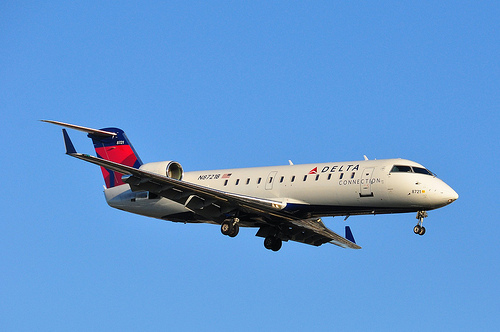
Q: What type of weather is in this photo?
A: It is clear.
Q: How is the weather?
A: It is clear.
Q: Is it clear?
A: Yes, it is clear.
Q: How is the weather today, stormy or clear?
A: It is clear.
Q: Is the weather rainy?
A: No, it is clear.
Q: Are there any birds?
A: No, there are no birds.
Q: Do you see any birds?
A: No, there are no birds.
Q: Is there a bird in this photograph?
A: No, there are no birds.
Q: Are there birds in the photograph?
A: No, there are no birds.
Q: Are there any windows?
A: Yes, there is a window.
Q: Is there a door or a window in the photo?
A: Yes, there is a window.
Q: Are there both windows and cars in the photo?
A: No, there is a window but no cars.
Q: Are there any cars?
A: No, there are no cars.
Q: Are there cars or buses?
A: No, there are no cars or buses.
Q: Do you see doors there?
A: Yes, there is a door.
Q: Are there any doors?
A: Yes, there is a door.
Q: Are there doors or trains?
A: Yes, there is a door.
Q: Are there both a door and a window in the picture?
A: Yes, there are both a door and a window.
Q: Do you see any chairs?
A: No, there are no chairs.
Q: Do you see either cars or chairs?
A: No, there are no chairs or cars.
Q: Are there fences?
A: No, there are no fences.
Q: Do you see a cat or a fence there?
A: No, there are no fences or cats.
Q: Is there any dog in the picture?
A: No, there are no dogs.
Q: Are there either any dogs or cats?
A: No, there are no dogs or cats.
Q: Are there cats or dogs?
A: No, there are no dogs or cats.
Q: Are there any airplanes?
A: Yes, there is an airplane.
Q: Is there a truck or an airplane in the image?
A: Yes, there is an airplane.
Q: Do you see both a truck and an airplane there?
A: No, there is an airplane but no trucks.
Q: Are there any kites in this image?
A: No, there are no kites.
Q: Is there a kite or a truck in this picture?
A: No, there are no kites or trucks.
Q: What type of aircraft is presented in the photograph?
A: The aircraft is an airplane.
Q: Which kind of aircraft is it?
A: The aircraft is an airplane.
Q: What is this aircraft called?
A: This is an airplane.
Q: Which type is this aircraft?
A: This is an airplane.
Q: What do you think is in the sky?
A: The airplane is in the sky.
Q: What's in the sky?
A: The airplane is in the sky.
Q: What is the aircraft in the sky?
A: The aircraft is an airplane.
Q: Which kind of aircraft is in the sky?
A: The aircraft is an airplane.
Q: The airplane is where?
A: The airplane is in the sky.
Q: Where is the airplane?
A: The airplane is in the sky.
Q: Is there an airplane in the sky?
A: Yes, there is an airplane in the sky.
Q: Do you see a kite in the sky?
A: No, there is an airplane in the sky.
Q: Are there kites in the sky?
A: No, there is an airplane in the sky.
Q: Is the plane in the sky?
A: Yes, the plane is in the sky.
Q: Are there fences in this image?
A: No, there are no fences.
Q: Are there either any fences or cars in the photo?
A: No, there are no fences or cars.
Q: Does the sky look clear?
A: Yes, the sky is clear.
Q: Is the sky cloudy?
A: No, the sky is clear.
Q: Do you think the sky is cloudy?
A: No, the sky is clear.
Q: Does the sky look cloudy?
A: No, the sky is clear.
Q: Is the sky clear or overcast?
A: The sky is clear.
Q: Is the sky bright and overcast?
A: No, the sky is bright but clear.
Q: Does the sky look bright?
A: Yes, the sky is bright.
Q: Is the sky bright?
A: Yes, the sky is bright.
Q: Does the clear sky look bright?
A: Yes, the sky is bright.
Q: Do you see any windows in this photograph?
A: Yes, there are windows.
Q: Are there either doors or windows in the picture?
A: Yes, there are windows.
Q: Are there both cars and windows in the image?
A: No, there are windows but no cars.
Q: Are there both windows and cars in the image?
A: No, there are windows but no cars.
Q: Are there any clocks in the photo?
A: No, there are no clocks.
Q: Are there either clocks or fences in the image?
A: No, there are no clocks or fences.